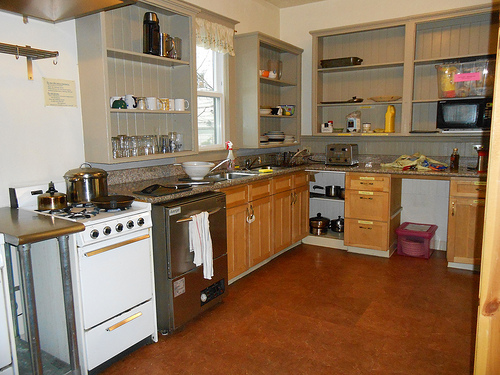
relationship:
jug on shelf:
[384, 103, 401, 130] [344, 104, 409, 149]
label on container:
[451, 75, 479, 85] [424, 99, 484, 102]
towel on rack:
[187, 208, 224, 286] [167, 196, 226, 236]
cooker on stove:
[63, 150, 112, 206] [58, 137, 162, 354]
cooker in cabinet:
[319, 182, 341, 196] [304, 165, 356, 232]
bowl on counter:
[175, 156, 216, 184] [171, 145, 224, 204]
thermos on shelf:
[140, 50, 164, 53] [114, 111, 181, 126]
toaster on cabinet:
[315, 136, 360, 168] [300, 135, 390, 190]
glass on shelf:
[111, 139, 121, 160] [107, 122, 168, 164]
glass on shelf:
[124, 133, 130, 154] [81, 105, 177, 175]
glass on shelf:
[137, 136, 144, 152] [100, 101, 164, 149]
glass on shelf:
[139, 134, 151, 158] [90, 104, 209, 171]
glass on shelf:
[145, 140, 155, 164] [104, 121, 188, 163]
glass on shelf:
[150, 131, 154, 151] [102, 118, 198, 167]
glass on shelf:
[159, 125, 172, 154] [108, 112, 197, 168]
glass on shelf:
[159, 134, 179, 167] [111, 113, 194, 163]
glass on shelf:
[169, 131, 179, 153] [106, 114, 191, 166]